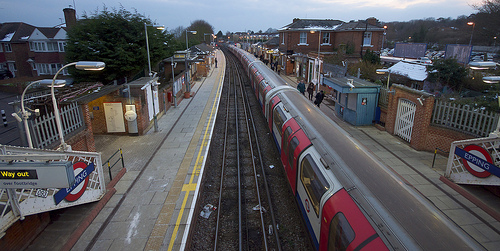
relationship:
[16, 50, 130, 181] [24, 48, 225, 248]
lampposts on left of platform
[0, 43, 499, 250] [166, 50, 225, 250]
pavement with line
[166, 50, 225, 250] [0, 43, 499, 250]
line in pavement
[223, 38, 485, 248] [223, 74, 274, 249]
train on track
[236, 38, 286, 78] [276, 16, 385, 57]
people standing in front of brick building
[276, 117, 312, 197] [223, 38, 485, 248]
red door on train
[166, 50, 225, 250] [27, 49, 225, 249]
line on pavement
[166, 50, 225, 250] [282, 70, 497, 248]
line on pavement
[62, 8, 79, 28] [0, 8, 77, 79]
chimney on brick building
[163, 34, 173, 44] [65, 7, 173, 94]
green leaf on tree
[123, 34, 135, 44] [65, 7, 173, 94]
green leaf on tree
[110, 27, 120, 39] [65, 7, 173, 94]
green leaf on tree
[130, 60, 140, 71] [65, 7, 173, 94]
green leaf on tree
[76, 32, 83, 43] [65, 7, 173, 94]
green leaf on tree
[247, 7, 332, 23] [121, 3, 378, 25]
clouds in sky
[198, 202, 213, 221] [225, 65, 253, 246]
garbage on tracks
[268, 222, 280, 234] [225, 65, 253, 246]
garbage on tracks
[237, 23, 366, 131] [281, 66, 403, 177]
people on platform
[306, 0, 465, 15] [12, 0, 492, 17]
clouds in sky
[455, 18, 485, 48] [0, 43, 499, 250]
lights in pavement